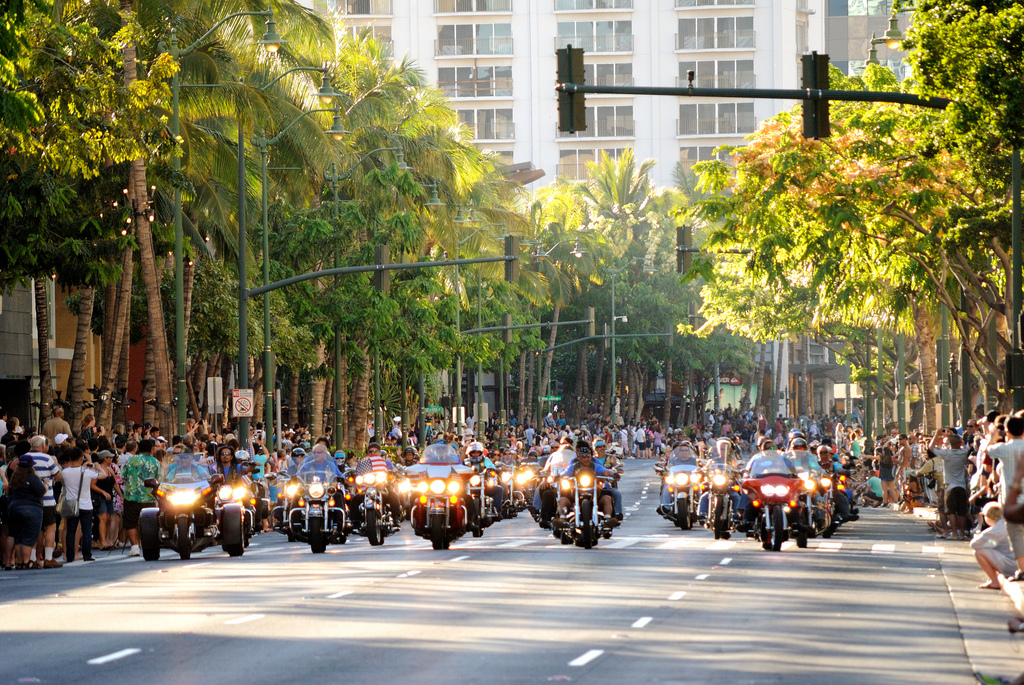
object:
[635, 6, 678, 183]
wall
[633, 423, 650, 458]
person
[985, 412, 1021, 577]
person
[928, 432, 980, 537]
person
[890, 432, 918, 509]
person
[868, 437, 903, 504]
person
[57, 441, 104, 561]
person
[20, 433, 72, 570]
person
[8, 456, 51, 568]
person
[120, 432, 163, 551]
person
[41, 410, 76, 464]
person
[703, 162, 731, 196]
leaves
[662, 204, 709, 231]
leaves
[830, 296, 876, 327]
leaves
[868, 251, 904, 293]
leaves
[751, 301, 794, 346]
leaves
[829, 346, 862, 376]
leaves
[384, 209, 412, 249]
leaves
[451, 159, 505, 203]
leaves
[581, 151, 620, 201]
leaves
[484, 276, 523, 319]
leaves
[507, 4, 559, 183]
wall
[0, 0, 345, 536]
building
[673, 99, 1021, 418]
tree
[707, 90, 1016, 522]
tree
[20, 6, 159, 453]
tree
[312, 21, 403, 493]
tree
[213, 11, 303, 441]
tree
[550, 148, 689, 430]
tree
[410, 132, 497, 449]
tree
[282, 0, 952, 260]
building